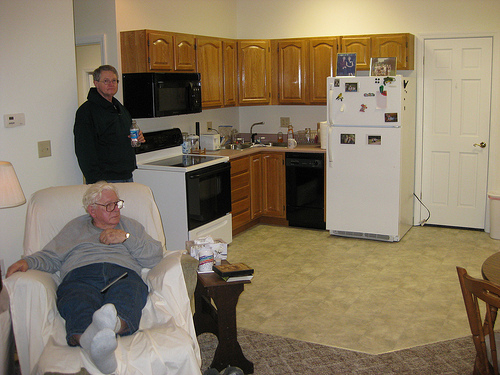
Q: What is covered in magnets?
A: The fridge.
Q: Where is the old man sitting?
A: On a white recliner.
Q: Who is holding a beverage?
A: A man.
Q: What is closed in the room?
A: The white door.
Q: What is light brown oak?
A: The cupboards.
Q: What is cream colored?
A: The laminate.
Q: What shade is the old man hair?
A: White.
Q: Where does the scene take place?
A: In a house.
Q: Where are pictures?
A: On a fridge.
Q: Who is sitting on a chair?
A: Old man.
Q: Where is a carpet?
A: On the floor.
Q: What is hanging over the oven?
A: Microwave.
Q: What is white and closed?
A: The door.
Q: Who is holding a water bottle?
A: Man standing.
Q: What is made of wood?
A: The cabinets.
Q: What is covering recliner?
A: White sheet.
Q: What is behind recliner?
A: Older man.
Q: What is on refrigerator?
A: Magnets.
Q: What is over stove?
A: Black microwave.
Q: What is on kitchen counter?
A: Stuff.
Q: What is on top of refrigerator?
A: Pictures.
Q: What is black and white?
A: Stove.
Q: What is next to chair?
A: End table.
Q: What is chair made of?
A: Wood.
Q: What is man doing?
A: Sitting.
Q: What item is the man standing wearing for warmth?
A: A jacket.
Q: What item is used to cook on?
A: A stove.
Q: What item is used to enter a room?
A: A door.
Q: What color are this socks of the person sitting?
A: White.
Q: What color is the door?
A: White.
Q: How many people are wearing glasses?
A: Two.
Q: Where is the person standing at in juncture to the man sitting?
A: Behind.